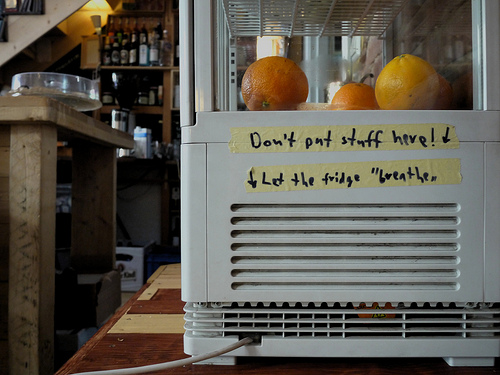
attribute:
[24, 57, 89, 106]
plastic tray — clear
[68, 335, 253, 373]
cord — gray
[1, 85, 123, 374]
table — wooden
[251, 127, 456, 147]
print — black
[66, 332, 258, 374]
power cord — white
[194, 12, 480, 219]
container — white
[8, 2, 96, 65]
staircase — wooden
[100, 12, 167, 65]
bottles — liquor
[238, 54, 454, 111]
oranges — round, delicious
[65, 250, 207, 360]
table — checkered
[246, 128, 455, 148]
letters — black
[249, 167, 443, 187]
writing — black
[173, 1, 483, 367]
fridge — white, small